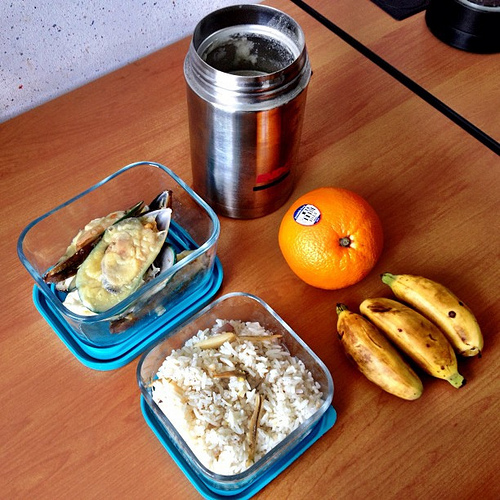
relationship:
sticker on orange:
[289, 201, 325, 228] [276, 185, 384, 294]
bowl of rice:
[136, 286, 342, 496] [144, 315, 324, 477]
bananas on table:
[332, 303, 424, 401] [1, 1, 498, 500]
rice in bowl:
[144, 315, 324, 477] [136, 286, 338, 492]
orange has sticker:
[276, 185, 384, 294] [289, 201, 325, 228]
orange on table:
[276, 185, 384, 294] [1, 1, 498, 500]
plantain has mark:
[358, 295, 467, 390] [365, 301, 393, 313]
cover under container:
[30, 219, 225, 372] [17, 159, 223, 347]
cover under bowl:
[139, 370, 340, 499] [136, 286, 338, 492]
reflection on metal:
[208, 70, 242, 221] [184, 2, 313, 223]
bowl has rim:
[136, 286, 338, 492] [139, 290, 335, 491]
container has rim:
[17, 159, 223, 347] [18, 156, 220, 322]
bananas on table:
[332, 270, 486, 405] [1, 1, 498, 500]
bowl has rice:
[136, 286, 338, 492] [144, 315, 324, 477]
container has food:
[17, 159, 223, 347] [43, 189, 211, 333]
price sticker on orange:
[289, 201, 325, 228] [276, 185, 384, 294]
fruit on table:
[276, 183, 485, 402] [1, 1, 498, 500]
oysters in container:
[45, 189, 212, 338] [17, 159, 223, 347]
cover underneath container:
[30, 219, 225, 372] [17, 159, 223, 347]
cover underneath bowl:
[139, 370, 340, 499] [136, 286, 338, 492]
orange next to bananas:
[276, 185, 384, 294] [332, 270, 486, 405]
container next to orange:
[181, 2, 309, 220] [276, 185, 384, 294]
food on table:
[18, 156, 486, 500] [1, 1, 498, 500]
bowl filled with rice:
[136, 286, 338, 492] [144, 315, 324, 477]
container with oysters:
[17, 159, 223, 347] [45, 189, 212, 338]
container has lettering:
[181, 2, 309, 220] [252, 149, 295, 183]